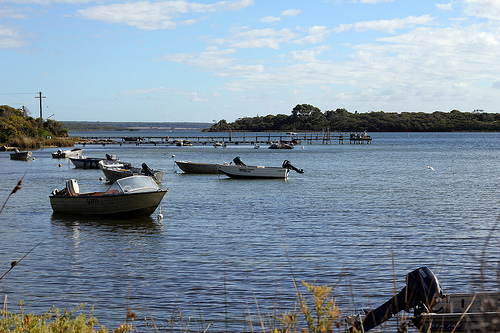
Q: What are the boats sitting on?
A: Water.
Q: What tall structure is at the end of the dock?
A: A telephone pole.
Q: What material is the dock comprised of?
A: Wood.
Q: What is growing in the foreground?
A: Plants.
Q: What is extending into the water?
A: Peninsula.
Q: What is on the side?
A: A black outboard boat motor.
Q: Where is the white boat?
A: In the water.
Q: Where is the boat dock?
A: In the water.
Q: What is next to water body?
A: Trees.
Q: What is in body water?
A: Boats.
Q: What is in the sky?
A: Clouds.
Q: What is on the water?
A: Boats.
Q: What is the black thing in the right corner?
A: Engine.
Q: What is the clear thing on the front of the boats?
A: Windshield.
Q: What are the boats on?
A: Water.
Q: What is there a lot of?
A: Parked boats.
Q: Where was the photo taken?
A: Outside somewhere.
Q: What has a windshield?
A: Speed boat.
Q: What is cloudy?
A: Sky.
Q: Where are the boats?
A: In water.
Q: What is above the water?
A: Sky.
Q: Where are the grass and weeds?
A: On the shore in the foreground.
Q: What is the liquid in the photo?
A: Water.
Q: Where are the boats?
A: In the water.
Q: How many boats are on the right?
A: 1.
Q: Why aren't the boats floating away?
A: They are anchored.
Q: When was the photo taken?
A: Daytime.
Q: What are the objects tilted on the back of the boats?
A: Motors.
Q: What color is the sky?
A: Blue.